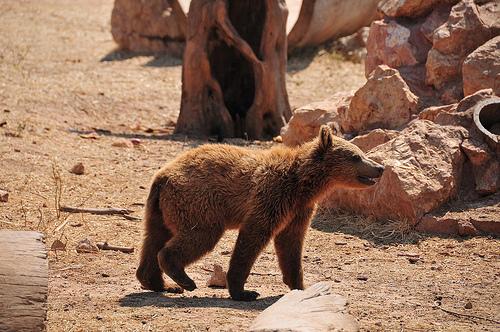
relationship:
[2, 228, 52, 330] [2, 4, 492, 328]
log on ground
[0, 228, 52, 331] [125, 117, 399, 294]
log behind bear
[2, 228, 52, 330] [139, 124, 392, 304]
log near bear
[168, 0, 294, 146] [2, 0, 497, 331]
stump in cage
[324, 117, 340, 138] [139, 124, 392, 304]
ear on bear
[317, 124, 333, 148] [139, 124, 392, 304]
ear on bear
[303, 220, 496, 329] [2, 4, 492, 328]
grass on ground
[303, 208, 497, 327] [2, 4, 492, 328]
sticks on ground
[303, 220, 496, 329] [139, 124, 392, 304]
grass in front of bear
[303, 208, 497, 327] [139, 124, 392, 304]
sticks in front of bear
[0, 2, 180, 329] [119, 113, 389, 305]
sticks behind bear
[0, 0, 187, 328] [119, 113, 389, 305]
grass behind bear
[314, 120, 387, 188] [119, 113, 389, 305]
head on bear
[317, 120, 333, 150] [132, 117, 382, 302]
ear on bear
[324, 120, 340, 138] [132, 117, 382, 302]
ear on bear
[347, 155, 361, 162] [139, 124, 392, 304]
eye on bear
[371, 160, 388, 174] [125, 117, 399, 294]
nose on bear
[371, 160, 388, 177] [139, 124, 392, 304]
snout on bear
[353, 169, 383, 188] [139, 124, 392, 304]
mouth on bear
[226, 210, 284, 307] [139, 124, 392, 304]
front leg on bear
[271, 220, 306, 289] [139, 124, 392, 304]
front leg on bear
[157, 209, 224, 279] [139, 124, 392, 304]
leg on bear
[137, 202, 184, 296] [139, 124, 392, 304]
back leg on bear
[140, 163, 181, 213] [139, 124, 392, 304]
tail on bear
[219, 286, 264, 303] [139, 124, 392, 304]
paw on bear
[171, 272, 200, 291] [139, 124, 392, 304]
paw on bear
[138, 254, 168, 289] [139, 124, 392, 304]
paw on bear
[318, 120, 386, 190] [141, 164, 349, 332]
head of bear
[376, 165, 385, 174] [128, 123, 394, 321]
nose of bear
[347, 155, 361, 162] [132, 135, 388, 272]
eye of bear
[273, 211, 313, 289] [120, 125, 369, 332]
front leg of bear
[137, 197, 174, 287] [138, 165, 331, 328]
back leg of bear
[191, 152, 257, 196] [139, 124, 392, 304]
fur on bear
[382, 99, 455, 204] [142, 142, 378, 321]
rocks next to bear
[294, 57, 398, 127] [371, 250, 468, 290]
rock sitting ground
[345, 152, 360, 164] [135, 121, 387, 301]
eye on bear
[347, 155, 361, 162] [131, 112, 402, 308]
eye of bear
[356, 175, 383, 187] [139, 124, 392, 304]
mouth of bear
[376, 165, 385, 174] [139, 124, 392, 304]
nose of bear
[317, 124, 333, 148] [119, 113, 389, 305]
ear of bear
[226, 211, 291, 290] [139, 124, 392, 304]
front leg of bear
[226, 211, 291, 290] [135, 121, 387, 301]
front leg of bear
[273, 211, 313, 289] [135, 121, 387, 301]
front leg of bear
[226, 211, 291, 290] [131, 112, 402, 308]
front leg of bear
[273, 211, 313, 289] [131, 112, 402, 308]
front leg of bear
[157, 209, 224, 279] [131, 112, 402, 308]
leg of bear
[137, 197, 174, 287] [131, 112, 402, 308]
back leg of bear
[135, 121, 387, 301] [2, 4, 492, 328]
bear on ground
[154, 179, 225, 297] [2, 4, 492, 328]
leg off ground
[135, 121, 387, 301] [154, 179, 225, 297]
bear with leg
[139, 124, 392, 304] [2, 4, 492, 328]
bear on ground